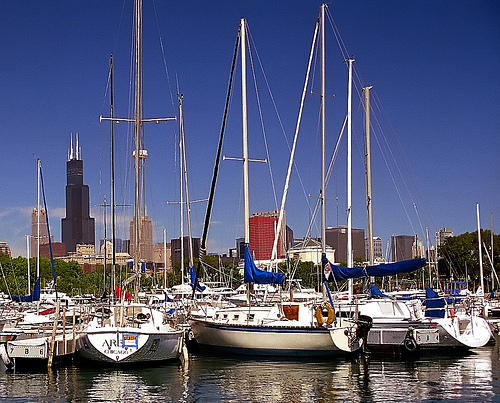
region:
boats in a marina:
[6, 3, 493, 393]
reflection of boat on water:
[85, 369, 167, 401]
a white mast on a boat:
[236, 17, 258, 262]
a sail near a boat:
[233, 200, 291, 291]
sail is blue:
[231, 238, 289, 294]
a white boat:
[189, 300, 362, 356]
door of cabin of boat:
[271, 293, 313, 323]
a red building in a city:
[241, 205, 296, 265]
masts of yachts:
[59, 3, 479, 288]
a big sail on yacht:
[321, 249, 433, 287]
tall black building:
[59, 134, 96, 260]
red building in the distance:
[242, 213, 279, 264]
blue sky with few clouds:
[0, 1, 496, 261]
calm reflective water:
[2, 338, 498, 400]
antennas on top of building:
[64, 127, 91, 167]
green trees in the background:
[0, 226, 497, 295]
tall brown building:
[25, 206, 59, 259]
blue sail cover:
[315, 251, 432, 281]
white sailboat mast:
[217, 14, 274, 305]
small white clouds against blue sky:
[2, 199, 244, 258]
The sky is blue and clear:
[283, 36, 474, 151]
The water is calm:
[152, 361, 272, 397]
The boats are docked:
[91, 305, 367, 397]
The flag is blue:
[227, 240, 293, 285]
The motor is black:
[345, 310, 380, 360]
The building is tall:
[48, 130, 104, 262]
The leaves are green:
[5, 257, 105, 304]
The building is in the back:
[222, 190, 310, 286]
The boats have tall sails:
[108, 50, 423, 321]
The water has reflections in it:
[179, 340, 334, 395]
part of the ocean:
[427, 368, 432, 374]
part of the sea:
[218, 363, 235, 386]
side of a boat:
[278, 335, 288, 351]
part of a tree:
[461, 251, 468, 268]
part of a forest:
[61, 265, 69, 272]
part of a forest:
[65, 263, 72, 275]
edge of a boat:
[309, 320, 326, 335]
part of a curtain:
[256, 267, 265, 275]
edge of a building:
[399, 240, 408, 260]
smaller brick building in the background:
[388, 229, 418, 264]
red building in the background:
[243, 208, 282, 263]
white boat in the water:
[183, 262, 370, 367]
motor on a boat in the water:
[348, 309, 374, 363]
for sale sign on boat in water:
[118, 327, 143, 352]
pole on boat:
[235, 12, 262, 308]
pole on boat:
[340, 57, 360, 298]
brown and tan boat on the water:
[3, 322, 89, 375]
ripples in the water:
[310, 359, 423, 400]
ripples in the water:
[113, 367, 173, 401]